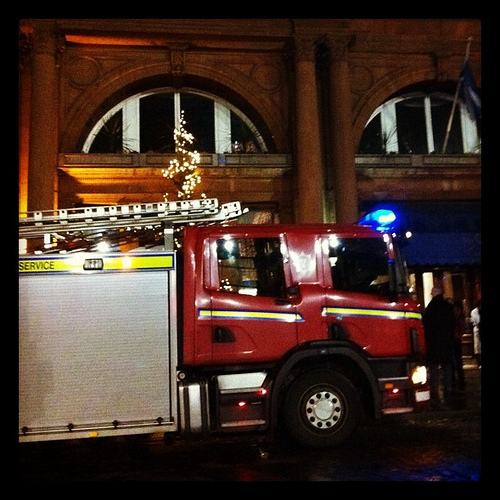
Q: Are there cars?
A: No, there are no cars.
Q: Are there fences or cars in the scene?
A: No, there are no cars or fences.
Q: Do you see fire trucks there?
A: Yes, there is a fire truck.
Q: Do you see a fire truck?
A: Yes, there is a fire truck.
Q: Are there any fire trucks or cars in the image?
A: Yes, there is a fire truck.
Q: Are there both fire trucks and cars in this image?
A: No, there is a fire truck but no cars.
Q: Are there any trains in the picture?
A: No, there are no trains.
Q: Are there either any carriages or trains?
A: No, there are no trains or carriages.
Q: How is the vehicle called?
A: The vehicle is a fire truck.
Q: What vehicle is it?
A: The vehicle is a fire truck.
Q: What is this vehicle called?
A: That is a fire truck.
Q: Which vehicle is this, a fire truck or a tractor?
A: That is a fire truck.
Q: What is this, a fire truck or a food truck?
A: This is a fire truck.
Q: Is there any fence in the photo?
A: No, there are no fences.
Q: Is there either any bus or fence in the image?
A: No, there are no fences or buses.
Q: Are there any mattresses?
A: No, there are no mattresses.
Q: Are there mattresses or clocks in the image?
A: No, there are no mattresses or clocks.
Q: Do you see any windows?
A: Yes, there is a window.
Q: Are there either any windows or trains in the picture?
A: Yes, there is a window.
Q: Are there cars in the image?
A: No, there are no cars.